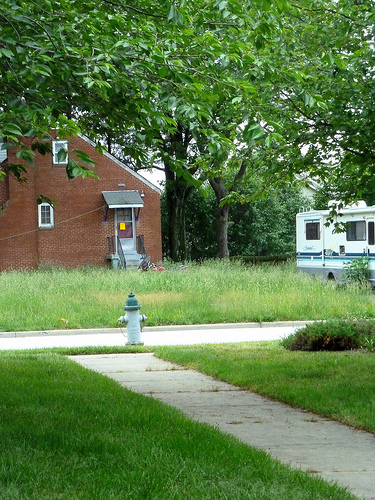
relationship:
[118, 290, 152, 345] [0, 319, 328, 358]
fire hydrant next to road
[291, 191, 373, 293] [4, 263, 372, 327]
rv parked in grass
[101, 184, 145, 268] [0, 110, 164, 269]
door into building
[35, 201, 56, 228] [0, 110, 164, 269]
window in building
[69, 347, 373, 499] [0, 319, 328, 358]
sidewalk to road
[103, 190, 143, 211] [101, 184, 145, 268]
cover over door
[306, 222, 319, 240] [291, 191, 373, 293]
window on rv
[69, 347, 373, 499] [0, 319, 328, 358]
sidewalk running to road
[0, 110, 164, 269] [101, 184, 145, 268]
building has door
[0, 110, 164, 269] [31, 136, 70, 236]
building has windows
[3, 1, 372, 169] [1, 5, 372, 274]
leaves on trees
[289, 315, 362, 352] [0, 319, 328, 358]
bush next to road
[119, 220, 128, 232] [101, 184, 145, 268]
note on door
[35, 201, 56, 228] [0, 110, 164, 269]
window on building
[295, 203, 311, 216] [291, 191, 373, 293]
ladder on rv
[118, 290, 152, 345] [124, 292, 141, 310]
fire hydrant has top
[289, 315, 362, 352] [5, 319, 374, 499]
bush in yard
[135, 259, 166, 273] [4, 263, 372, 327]
motorcycle in grass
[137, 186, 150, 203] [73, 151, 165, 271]
light on wall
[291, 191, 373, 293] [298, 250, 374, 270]
rv has lines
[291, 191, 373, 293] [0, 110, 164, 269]
rv parked outside of building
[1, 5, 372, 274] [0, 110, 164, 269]
trees next to building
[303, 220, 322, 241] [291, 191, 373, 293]
window in rv